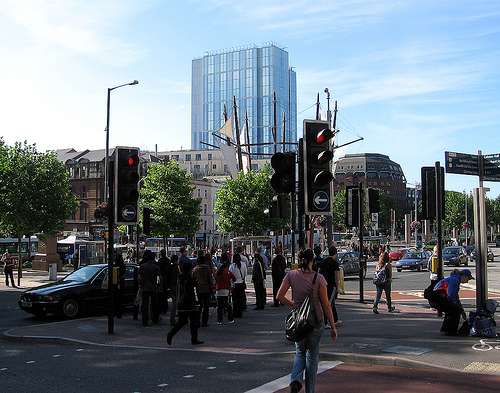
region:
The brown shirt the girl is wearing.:
[278, 267, 327, 322]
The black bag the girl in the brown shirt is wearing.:
[287, 283, 327, 338]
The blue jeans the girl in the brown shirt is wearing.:
[295, 322, 317, 389]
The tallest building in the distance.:
[181, 57, 297, 152]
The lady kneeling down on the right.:
[422, 262, 477, 326]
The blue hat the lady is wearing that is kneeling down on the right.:
[460, 265, 476, 280]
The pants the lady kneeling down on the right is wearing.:
[425, 290, 460, 328]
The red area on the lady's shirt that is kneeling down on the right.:
[432, 280, 449, 295]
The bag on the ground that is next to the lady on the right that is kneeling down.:
[462, 292, 497, 342]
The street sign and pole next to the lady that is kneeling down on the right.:
[444, 142, 499, 304]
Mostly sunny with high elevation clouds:
[3, 12, 483, 153]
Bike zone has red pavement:
[365, 280, 499, 302]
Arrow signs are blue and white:
[115, 191, 340, 218]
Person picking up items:
[424, 268, 498, 338]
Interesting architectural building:
[335, 150, 426, 231]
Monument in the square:
[31, 228, 70, 280]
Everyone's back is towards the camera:
[109, 244, 412, 358]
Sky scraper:
[182, 39, 305, 154]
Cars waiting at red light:
[325, 239, 495, 277]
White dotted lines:
[1, 347, 243, 391]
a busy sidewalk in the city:
[43, 50, 485, 391]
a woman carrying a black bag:
[266, 245, 336, 390]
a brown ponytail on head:
[292, 249, 311, 268]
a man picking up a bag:
[423, 255, 474, 338]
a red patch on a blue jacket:
[441, 282, 448, 289]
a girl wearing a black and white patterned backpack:
[371, 251, 396, 316]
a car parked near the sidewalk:
[48, 274, 102, 307]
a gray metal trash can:
[44, 260, 64, 280]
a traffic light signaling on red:
[299, 110, 333, 225]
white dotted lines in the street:
[163, 350, 260, 383]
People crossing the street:
[131, 241, 391, 386]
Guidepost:
[440, 145, 495, 220]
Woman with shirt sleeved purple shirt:
[280, 242, 335, 387]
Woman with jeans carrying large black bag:
[281, 246, 326, 386]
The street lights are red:
[107, 121, 337, 241]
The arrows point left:
[111, 185, 346, 211]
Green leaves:
[0, 130, 499, 235]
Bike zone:
[460, 330, 497, 353]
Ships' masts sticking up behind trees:
[200, 85, 355, 180]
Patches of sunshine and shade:
[3, 267, 493, 392]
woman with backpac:
[370, 249, 399, 317]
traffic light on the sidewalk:
[104, 144, 144, 336]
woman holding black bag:
[274, 247, 341, 391]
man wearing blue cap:
[424, 268, 474, 337]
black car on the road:
[16, 261, 140, 320]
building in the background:
[189, 41, 303, 160]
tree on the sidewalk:
[0, 136, 83, 286]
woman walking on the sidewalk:
[371, 251, 398, 318]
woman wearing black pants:
[164, 263, 206, 347]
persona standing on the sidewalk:
[0, 248, 20, 291]